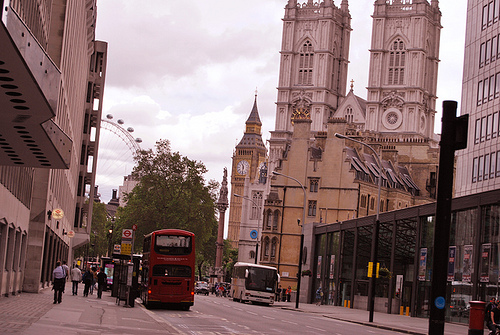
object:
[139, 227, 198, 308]
bus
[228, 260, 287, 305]
bus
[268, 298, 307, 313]
curb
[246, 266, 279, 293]
windshield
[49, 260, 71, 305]
pedestrian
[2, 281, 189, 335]
sidewalk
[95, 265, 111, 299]
pedestrian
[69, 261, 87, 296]
pedestrian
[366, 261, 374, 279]
sign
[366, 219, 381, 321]
pole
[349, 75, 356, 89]
steeple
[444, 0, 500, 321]
building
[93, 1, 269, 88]
clouds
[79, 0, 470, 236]
sky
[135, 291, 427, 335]
street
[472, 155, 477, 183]
windows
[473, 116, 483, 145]
windows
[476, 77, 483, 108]
windows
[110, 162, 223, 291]
tree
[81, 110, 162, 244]
ferris wheel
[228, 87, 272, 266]
clock tower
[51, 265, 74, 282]
shirt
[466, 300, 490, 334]
can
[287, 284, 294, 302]
person